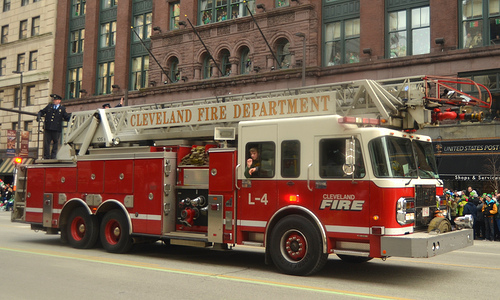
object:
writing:
[129, 93, 329, 126]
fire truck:
[20, 72, 494, 276]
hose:
[426, 216, 453, 234]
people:
[439, 186, 500, 244]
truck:
[14, 71, 494, 277]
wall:
[425, 126, 499, 139]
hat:
[49, 93, 63, 101]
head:
[49, 94, 63, 105]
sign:
[319, 193, 367, 212]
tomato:
[146, 127, 447, 250]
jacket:
[37, 104, 74, 132]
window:
[281, 140, 300, 178]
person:
[243, 147, 261, 179]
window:
[244, 142, 276, 179]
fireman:
[35, 93, 70, 156]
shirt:
[52, 103, 60, 110]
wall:
[0, 0, 52, 150]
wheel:
[265, 209, 330, 277]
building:
[1, 0, 499, 198]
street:
[0, 206, 498, 298]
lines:
[2, 244, 393, 299]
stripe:
[26, 207, 413, 237]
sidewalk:
[461, 239, 500, 249]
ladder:
[18, 62, 483, 254]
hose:
[429, 95, 484, 124]